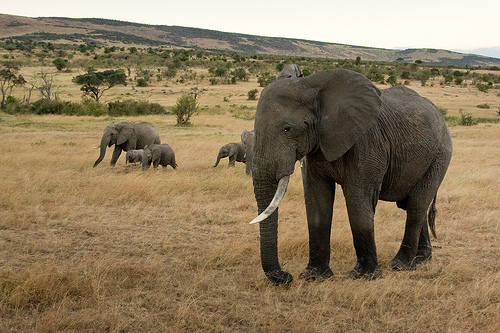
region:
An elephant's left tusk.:
[257, 175, 294, 231]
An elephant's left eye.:
[282, 121, 292, 131]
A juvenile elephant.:
[143, 146, 176, 169]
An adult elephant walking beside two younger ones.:
[90, 118, 188, 171]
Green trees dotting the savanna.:
[105, 46, 222, 71]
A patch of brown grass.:
[25, 174, 204, 319]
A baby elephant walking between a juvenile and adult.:
[125, 147, 140, 164]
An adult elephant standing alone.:
[226, 67, 453, 279]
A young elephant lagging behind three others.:
[210, 140, 240, 166]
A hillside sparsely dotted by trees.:
[129, 21, 291, 53]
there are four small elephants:
[123, 125, 274, 180]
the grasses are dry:
[55, 194, 199, 308]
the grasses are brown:
[37, 216, 164, 330]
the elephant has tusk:
[220, 60, 440, 327]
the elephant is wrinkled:
[234, 59, 479, 297]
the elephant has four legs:
[295, 150, 455, 265]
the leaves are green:
[78, 69, 118, 86]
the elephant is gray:
[236, 56, 462, 308]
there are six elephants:
[35, 32, 464, 312]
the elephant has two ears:
[217, 54, 399, 293]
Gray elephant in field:
[236, 56, 452, 293]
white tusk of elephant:
[249, 175, 287, 227]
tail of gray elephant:
[430, 189, 440, 245]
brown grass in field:
[24, 195, 186, 318]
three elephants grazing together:
[88, 122, 178, 174]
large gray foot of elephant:
[301, 254, 336, 284]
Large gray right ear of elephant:
[305, 62, 381, 164]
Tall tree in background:
[73, 66, 125, 112]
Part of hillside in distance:
[395, 43, 499, 73]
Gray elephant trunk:
[248, 165, 293, 286]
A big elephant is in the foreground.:
[233, 61, 477, 308]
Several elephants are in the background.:
[86, 112, 283, 189]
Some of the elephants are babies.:
[117, 137, 259, 174]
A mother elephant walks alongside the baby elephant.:
[78, 107, 194, 180]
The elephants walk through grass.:
[1, 115, 498, 332]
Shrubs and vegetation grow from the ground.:
[0, 48, 246, 125]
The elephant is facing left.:
[217, 59, 487, 299]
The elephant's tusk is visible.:
[234, 162, 301, 232]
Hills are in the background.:
[0, 7, 499, 62]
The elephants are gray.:
[84, 48, 470, 298]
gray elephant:
[204, 86, 449, 297]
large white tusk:
[253, 165, 296, 249]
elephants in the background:
[58, 90, 260, 225]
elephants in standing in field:
[18, 115, 465, 317]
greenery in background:
[6, 90, 205, 124]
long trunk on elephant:
[248, 132, 293, 293]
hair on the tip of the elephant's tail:
[426, 200, 452, 254]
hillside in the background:
[13, 30, 496, 100]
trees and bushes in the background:
[41, 40, 449, 87]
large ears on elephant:
[272, 56, 397, 180]